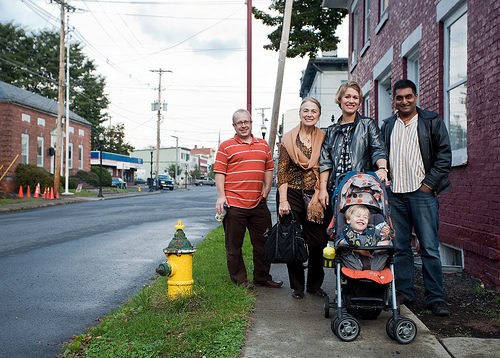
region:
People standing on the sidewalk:
[206, 74, 461, 306]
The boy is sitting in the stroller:
[321, 163, 423, 344]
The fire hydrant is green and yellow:
[154, 213, 205, 296]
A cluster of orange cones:
[13, 177, 71, 205]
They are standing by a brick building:
[216, 10, 490, 335]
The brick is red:
[381, 13, 488, 255]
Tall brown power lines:
[31, 1, 186, 199]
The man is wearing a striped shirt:
[204, 108, 284, 220]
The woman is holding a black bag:
[271, 98, 334, 303]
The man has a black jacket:
[369, 75, 461, 211]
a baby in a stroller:
[341, 152, 415, 341]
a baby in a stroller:
[276, 152, 356, 339]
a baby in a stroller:
[306, 192, 387, 347]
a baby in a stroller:
[332, 235, 362, 342]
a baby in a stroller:
[335, 245, 355, 320]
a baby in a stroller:
[341, 233, 394, 355]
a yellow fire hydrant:
[153, 213, 202, 305]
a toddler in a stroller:
[333, 178, 413, 342]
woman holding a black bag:
[261, 197, 314, 262]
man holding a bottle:
[211, 197, 236, 227]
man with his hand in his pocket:
[399, 177, 466, 214]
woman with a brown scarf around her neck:
[285, 115, 327, 167]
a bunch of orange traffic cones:
[15, 177, 65, 205]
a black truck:
[148, 171, 176, 195]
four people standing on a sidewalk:
[203, 68, 474, 330]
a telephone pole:
[23, 0, 88, 180]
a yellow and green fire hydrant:
[153, 217, 202, 301]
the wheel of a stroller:
[327, 306, 364, 345]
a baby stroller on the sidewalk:
[318, 163, 423, 343]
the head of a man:
[388, 72, 423, 119]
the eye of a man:
[403, 91, 414, 101]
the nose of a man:
[398, 94, 410, 106]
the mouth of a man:
[398, 100, 411, 110]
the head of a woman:
[331, 75, 366, 116]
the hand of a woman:
[316, 185, 331, 212]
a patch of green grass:
[64, 220, 269, 357]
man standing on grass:
[211, 111, 286, 291]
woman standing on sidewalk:
[268, 92, 333, 296]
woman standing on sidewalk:
[327, 85, 381, 217]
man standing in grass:
[369, 79, 456, 316]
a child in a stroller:
[324, 167, 413, 342]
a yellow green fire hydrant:
[155, 218, 190, 297]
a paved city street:
[4, 169, 234, 349]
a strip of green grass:
[71, 210, 258, 352]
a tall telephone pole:
[48, 0, 77, 198]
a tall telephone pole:
[146, 62, 171, 178]